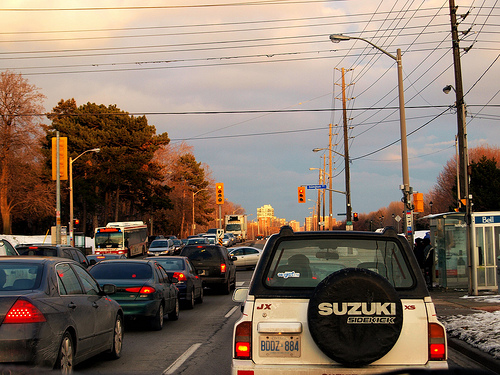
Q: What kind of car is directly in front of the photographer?
A: A Suzuki Sidekick.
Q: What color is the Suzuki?
A: White.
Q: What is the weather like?
A: Cloudy.